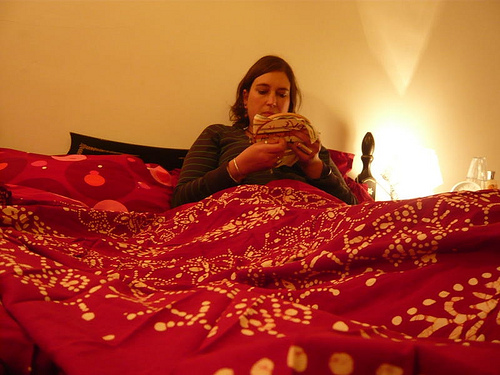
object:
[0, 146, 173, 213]
pillow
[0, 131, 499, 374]
bed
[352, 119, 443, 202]
lighted corner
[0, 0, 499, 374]
bedroom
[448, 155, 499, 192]
items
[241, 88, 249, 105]
ear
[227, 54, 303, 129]
brown hair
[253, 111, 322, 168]
book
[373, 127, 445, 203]
light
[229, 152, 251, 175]
wrist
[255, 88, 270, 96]
eyes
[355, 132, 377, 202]
bed post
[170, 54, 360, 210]
lady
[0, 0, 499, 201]
wall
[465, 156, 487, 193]
glassware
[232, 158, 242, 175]
band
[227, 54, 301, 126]
head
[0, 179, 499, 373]
blanket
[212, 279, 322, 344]
design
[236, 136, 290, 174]
hands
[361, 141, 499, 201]
bedside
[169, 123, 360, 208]
sweater